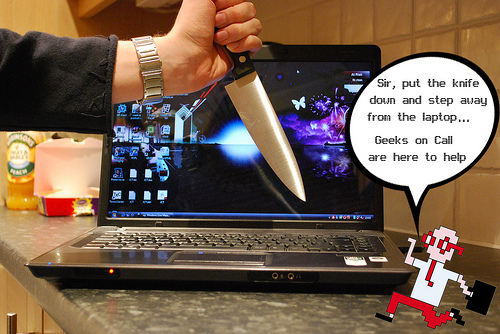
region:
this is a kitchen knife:
[202, 33, 333, 217]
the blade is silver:
[222, 87, 322, 209]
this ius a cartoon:
[319, 40, 487, 315]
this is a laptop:
[70, 122, 360, 323]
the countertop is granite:
[122, 290, 202, 330]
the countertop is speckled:
[120, 298, 190, 329]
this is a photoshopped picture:
[30, 50, 470, 280]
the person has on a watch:
[110, 17, 185, 90]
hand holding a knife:
[176, 9, 343, 214]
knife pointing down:
[200, 17, 332, 225]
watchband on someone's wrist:
[94, 25, 194, 114]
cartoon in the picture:
[329, 36, 487, 330]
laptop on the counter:
[32, 24, 451, 295]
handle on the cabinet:
[7, 306, 29, 332]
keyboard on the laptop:
[89, 219, 406, 271]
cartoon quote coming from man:
[341, 33, 496, 250]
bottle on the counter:
[10, 122, 55, 222]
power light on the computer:
[101, 264, 122, 277]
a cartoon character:
[367, 218, 495, 328]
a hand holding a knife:
[161, 0, 321, 219]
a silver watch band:
[127, 28, 168, 115]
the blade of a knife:
[223, 71, 321, 214]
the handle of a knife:
[221, 44, 256, 78]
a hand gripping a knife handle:
[178, 0, 270, 76]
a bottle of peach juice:
[6, 133, 38, 212]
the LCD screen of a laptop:
[114, 38, 375, 228]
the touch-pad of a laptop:
[176, 251, 271, 268]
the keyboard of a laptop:
[91, 225, 358, 252]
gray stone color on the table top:
[128, 301, 239, 323]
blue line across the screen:
[104, 211, 241, 221]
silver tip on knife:
[272, 184, 322, 206]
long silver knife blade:
[213, 75, 313, 212]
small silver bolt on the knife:
[213, 45, 258, 68]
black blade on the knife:
[226, 47, 253, 64]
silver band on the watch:
[126, 34, 171, 111]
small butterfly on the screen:
[285, 93, 317, 108]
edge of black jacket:
[77, 83, 122, 133]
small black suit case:
[458, 276, 495, 313]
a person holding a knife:
[5, 5, 310, 206]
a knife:
[224, 38, 308, 202]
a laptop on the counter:
[56, 29, 398, 280]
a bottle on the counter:
[8, 129, 48, 211]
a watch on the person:
[126, 28, 174, 115]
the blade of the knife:
[226, 79, 311, 200]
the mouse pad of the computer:
[168, 246, 270, 276]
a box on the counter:
[30, 131, 93, 201]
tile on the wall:
[269, 3, 495, 41]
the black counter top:
[91, 296, 357, 332]